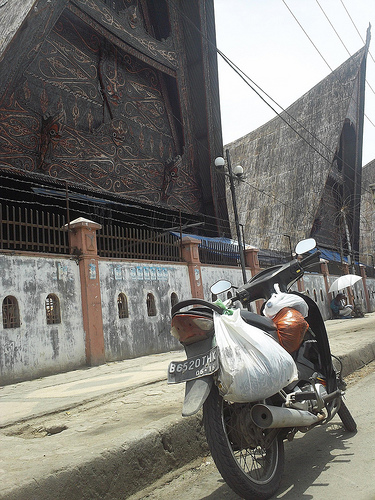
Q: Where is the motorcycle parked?
A: Street.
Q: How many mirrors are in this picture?
A: 2.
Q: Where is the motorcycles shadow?
A: Street.